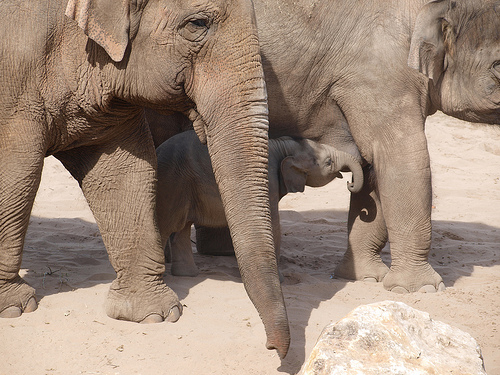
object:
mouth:
[182, 103, 203, 144]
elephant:
[1, 0, 289, 358]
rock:
[305, 300, 483, 375]